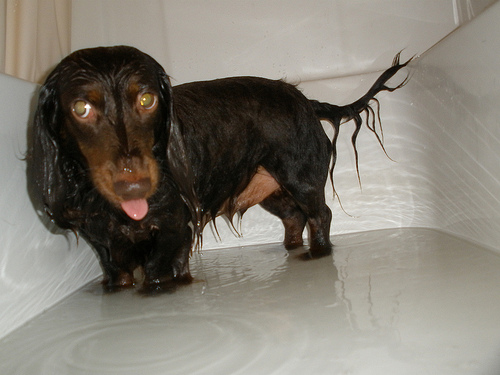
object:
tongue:
[120, 199, 150, 221]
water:
[0, 227, 500, 375]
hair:
[190, 91, 263, 150]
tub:
[0, 2, 500, 375]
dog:
[26, 45, 419, 298]